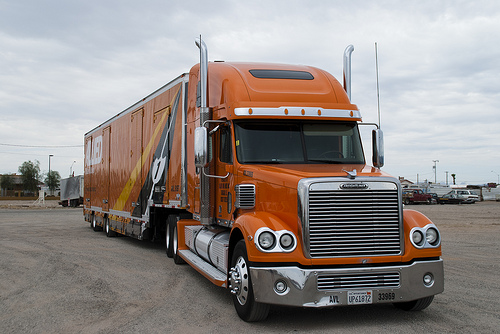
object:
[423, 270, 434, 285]
foglight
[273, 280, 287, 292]
foglight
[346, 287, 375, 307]
license plate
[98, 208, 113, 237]
wheel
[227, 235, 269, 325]
black tire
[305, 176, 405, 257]
grill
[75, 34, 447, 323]
truck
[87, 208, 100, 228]
wheel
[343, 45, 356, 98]
exhaust pipe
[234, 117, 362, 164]
windshield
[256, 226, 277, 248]
headlight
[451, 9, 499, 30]
clouds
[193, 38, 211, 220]
exhaust pipe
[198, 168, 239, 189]
handle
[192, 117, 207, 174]
chrome mirror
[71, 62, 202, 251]
trailer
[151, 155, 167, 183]
sign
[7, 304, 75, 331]
road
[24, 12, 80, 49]
clouds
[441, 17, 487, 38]
sky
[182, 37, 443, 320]
semi truck